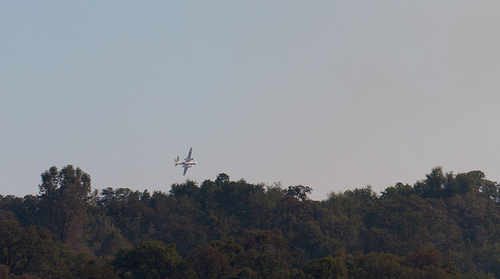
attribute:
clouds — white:
[342, 27, 463, 97]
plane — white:
[167, 149, 202, 174]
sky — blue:
[111, 9, 478, 134]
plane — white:
[175, 147, 197, 177]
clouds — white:
[328, 21, 455, 96]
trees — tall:
[214, 161, 475, 222]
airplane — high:
[181, 141, 212, 181]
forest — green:
[1, 165, 498, 277]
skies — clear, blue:
[278, 72, 433, 149]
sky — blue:
[13, 15, 471, 222]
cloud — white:
[146, 79, 233, 107]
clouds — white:
[237, 82, 448, 158]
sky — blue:
[1, 2, 493, 192]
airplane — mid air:
[173, 146, 198, 176]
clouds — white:
[248, 71, 293, 126]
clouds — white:
[190, 17, 498, 167]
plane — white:
[166, 145, 198, 177]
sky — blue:
[115, 74, 477, 183]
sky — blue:
[94, 106, 429, 198]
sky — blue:
[86, 82, 414, 177]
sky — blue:
[141, 121, 385, 196]